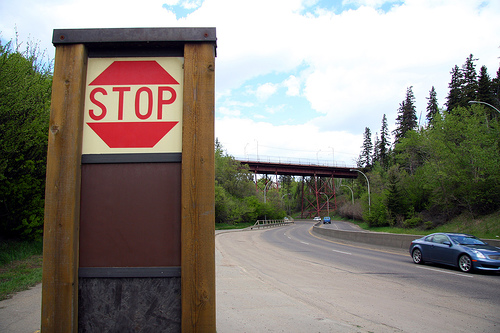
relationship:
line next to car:
[411, 260, 474, 280] [409, 230, 497, 274]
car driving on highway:
[409, 230, 497, 274] [218, 216, 498, 331]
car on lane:
[323, 217, 331, 224] [324, 220, 394, 232]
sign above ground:
[81, 55, 187, 160] [4, 216, 498, 330]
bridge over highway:
[230, 158, 370, 218] [218, 216, 498, 331]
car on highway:
[409, 232, 500, 274] [250, 160, 434, 320]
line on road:
[335, 240, 358, 255] [260, 217, 459, 320]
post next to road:
[346, 167, 373, 218] [215, 215, 495, 329]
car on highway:
[409, 230, 497, 274] [218, 216, 498, 331]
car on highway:
[313, 217, 321, 222] [218, 216, 498, 331]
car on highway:
[323, 217, 331, 224] [218, 216, 498, 331]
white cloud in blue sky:
[0, 0, 499, 160] [214, 58, 328, 127]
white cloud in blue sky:
[182, 0, 499, 117] [214, 58, 328, 127]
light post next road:
[346, 163, 373, 213] [246, 212, 489, 325]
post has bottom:
[175, 42, 220, 331] [70, 255, 188, 331]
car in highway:
[312, 215, 324, 220] [247, 190, 498, 323]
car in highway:
[323, 215, 331, 222] [247, 190, 498, 323]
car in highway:
[409, 232, 500, 274] [247, 190, 498, 323]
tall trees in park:
[424, 86, 443, 121] [10, 34, 499, 263]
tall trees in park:
[377, 112, 393, 166] [10, 34, 499, 263]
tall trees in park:
[359, 123, 371, 165] [10, 34, 499, 263]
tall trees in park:
[395, 83, 418, 135] [10, 34, 499, 263]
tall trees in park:
[446, 64, 464, 109] [10, 34, 499, 263]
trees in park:
[444, 57, 491, 112] [10, 34, 499, 263]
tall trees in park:
[443, 64, 464, 111] [231, 152, 370, 222]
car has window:
[409, 232, 500, 274] [432, 232, 451, 251]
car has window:
[409, 230, 497, 274] [450, 234, 484, 246]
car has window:
[409, 232, 500, 274] [443, 230, 488, 249]